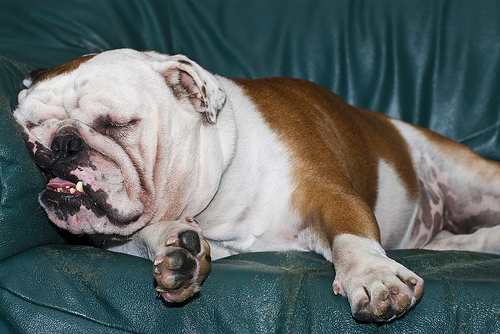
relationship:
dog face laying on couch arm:
[40, 80, 151, 234] [0, 2, 118, 259]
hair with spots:
[97, 57, 161, 99] [157, 53, 225, 125]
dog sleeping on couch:
[4, 38, 498, 332] [2, 2, 497, 332]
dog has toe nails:
[4, 38, 498, 332] [148, 245, 164, 301]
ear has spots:
[159, 42, 235, 129] [177, 54, 215, 108]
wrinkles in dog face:
[113, 138, 185, 219] [13, 80, 150, 234]